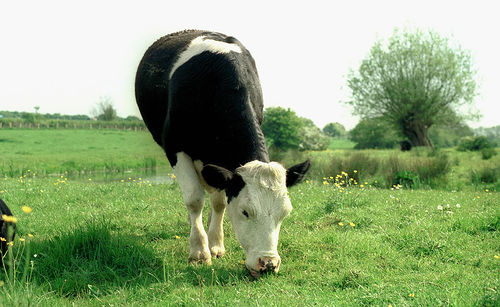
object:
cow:
[132, 29, 313, 279]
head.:
[200, 159, 313, 279]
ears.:
[287, 158, 312, 186]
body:
[134, 27, 274, 187]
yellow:
[316, 169, 364, 192]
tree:
[346, 29, 479, 149]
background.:
[0, 3, 495, 153]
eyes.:
[241, 209, 250, 218]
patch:
[11, 218, 171, 298]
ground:
[4, 130, 493, 305]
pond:
[4, 154, 176, 190]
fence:
[1, 115, 149, 138]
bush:
[464, 160, 498, 185]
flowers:
[21, 205, 32, 213]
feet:
[187, 245, 214, 266]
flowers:
[354, 170, 358, 173]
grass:
[3, 127, 471, 305]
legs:
[173, 160, 210, 257]